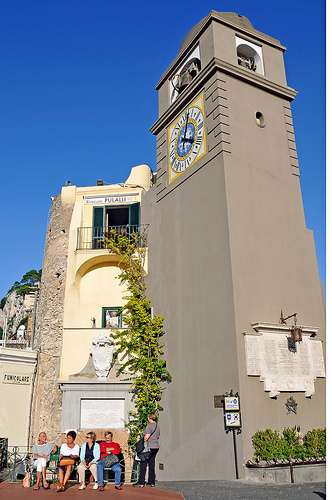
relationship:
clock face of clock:
[168, 107, 205, 173] [166, 102, 208, 174]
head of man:
[102, 427, 112, 441] [95, 418, 129, 493]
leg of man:
[113, 463, 123, 484] [98, 425, 126, 485]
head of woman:
[81, 426, 96, 442] [77, 425, 101, 490]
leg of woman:
[79, 463, 83, 486] [72, 421, 104, 491]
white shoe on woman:
[76, 481, 89, 488] [74, 432, 108, 491]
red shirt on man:
[101, 443, 122, 453] [97, 426, 127, 491]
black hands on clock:
[177, 111, 194, 143] [155, 94, 222, 179]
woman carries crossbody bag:
[132, 409, 161, 487] [135, 440, 150, 463]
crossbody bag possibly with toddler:
[135, 440, 150, 463] [137, 443, 155, 457]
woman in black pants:
[132, 409, 161, 487] [137, 443, 160, 479]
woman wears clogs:
[132, 409, 161, 487] [128, 479, 161, 486]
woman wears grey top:
[128, 405, 167, 487] [140, 417, 159, 453]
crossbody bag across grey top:
[133, 424, 149, 457] [140, 417, 159, 453]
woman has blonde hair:
[132, 409, 161, 487] [144, 409, 154, 421]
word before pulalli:
[85, 197, 104, 206] [103, 193, 128, 204]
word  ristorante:
[85, 197, 104, 206] [86, 195, 104, 208]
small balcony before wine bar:
[77, 226, 151, 244] [93, 201, 138, 245]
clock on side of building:
[157, 94, 214, 177] [152, 9, 324, 483]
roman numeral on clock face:
[193, 121, 205, 130] [161, 94, 211, 170]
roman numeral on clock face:
[195, 132, 210, 148] [164, 96, 209, 179]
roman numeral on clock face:
[192, 112, 204, 123] [164, 96, 209, 179]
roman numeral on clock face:
[181, 157, 191, 168] [163, 99, 213, 172]